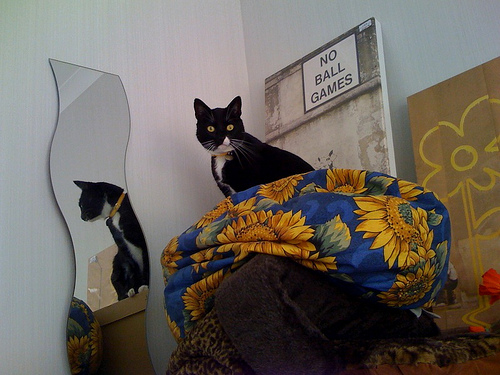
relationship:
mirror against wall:
[48, 58, 158, 374] [1, 1, 257, 372]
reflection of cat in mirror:
[72, 180, 150, 301] [48, 58, 158, 374]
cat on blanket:
[193, 96, 316, 198] [161, 169, 450, 344]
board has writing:
[263, 17, 397, 177] [311, 50, 352, 103]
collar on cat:
[213, 151, 234, 161] [193, 96, 316, 198]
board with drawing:
[263, 17, 397, 177] [314, 149, 339, 170]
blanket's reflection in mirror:
[67, 296, 103, 375] [48, 58, 158, 374]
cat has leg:
[193, 96, 316, 198] [219, 188, 237, 198]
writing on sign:
[311, 50, 352, 103] [301, 32, 361, 116]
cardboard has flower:
[406, 58, 500, 334] [419, 94, 500, 328]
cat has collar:
[193, 96, 316, 198] [213, 151, 234, 161]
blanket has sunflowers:
[161, 169, 450, 344] [161, 167, 449, 347]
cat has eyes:
[193, 96, 316, 198] [207, 124, 234, 132]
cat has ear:
[193, 96, 316, 198] [226, 95, 243, 118]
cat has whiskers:
[193, 96, 316, 198] [193, 138, 257, 166]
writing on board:
[311, 50, 352, 103] [263, 17, 397, 177]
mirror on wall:
[48, 58, 158, 374] [1, 1, 257, 372]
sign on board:
[301, 32, 361, 116] [263, 17, 397, 177]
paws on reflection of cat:
[128, 284, 148, 297] [72, 180, 150, 301]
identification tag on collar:
[225, 154, 233, 162] [213, 151, 234, 161]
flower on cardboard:
[419, 94, 500, 328] [406, 58, 500, 334]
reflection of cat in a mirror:
[72, 180, 150, 301] [48, 58, 158, 374]